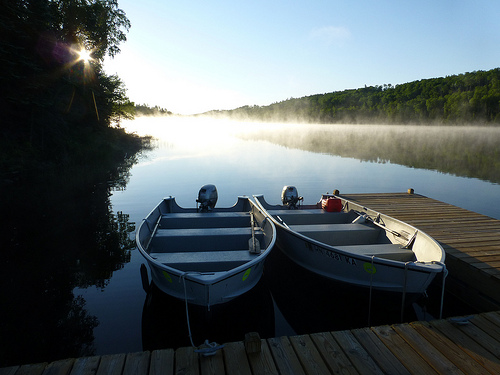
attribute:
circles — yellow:
[155, 266, 255, 291]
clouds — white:
[128, 49, 236, 123]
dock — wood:
[421, 202, 485, 374]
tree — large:
[190, 70, 499, 125]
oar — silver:
[241, 207, 261, 260]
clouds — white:
[306, 18, 354, 50]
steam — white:
[158, 99, 346, 158]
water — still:
[72, 119, 497, 357]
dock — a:
[0, 189, 500, 374]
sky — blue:
[98, 0, 498, 115]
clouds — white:
[116, 54, 306, 111]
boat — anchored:
[275, 222, 395, 310]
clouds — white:
[165, 81, 235, 113]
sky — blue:
[162, 29, 269, 81]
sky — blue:
[86, 0, 441, 63]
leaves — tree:
[55, 0, 129, 72]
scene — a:
[4, 99, 498, 371]